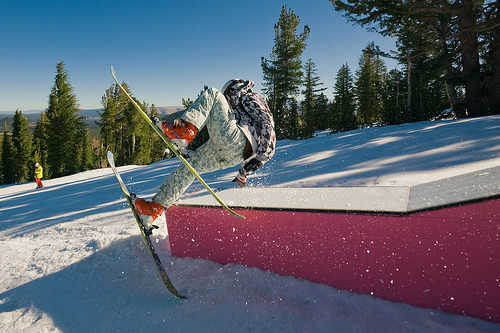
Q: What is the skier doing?
A: Jumping.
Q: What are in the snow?
A: Tree.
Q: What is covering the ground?
A: Snow.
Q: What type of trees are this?
A: Pine.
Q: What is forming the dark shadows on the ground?
A: The pine trees.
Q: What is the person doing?
A: A stunt.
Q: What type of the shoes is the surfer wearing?
A: Red boots.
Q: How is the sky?
A: Blue and clear.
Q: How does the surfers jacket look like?
A: White and black.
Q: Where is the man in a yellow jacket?
A: Next to the pine trees.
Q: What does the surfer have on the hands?
A: Black gloves.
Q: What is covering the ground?
A: White snow.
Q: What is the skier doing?
A: Falling backwards.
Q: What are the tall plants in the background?
A: Pine trees.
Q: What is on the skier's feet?
A: Red snowshoes.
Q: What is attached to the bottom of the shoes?
A: Snow skis.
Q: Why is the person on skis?
A: They are skiing.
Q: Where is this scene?
A: Ski slope.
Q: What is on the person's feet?
A: Skis.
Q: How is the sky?
A: Clear.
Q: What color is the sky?
A: Blue.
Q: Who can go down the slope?
A: People on skis.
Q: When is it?
A: Day time.